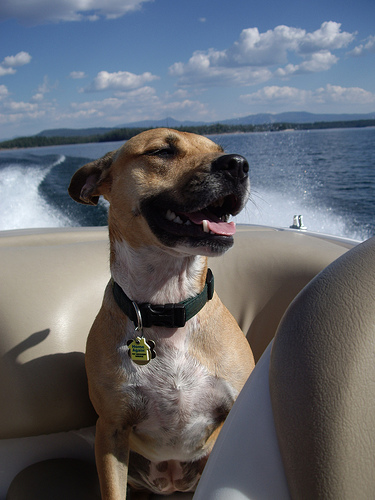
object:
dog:
[56, 96, 281, 461]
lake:
[2, 82, 359, 261]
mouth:
[150, 166, 253, 254]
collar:
[71, 234, 245, 343]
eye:
[136, 121, 197, 169]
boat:
[1, 140, 348, 409]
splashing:
[257, 159, 349, 222]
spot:
[143, 290, 224, 410]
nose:
[187, 144, 253, 189]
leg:
[75, 382, 142, 498]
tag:
[111, 326, 155, 371]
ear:
[35, 152, 125, 208]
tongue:
[143, 194, 261, 267]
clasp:
[142, 282, 216, 333]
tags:
[60, 262, 243, 374]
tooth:
[176, 206, 223, 261]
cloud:
[201, 19, 326, 100]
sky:
[102, 13, 296, 98]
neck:
[63, 212, 263, 319]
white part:
[115, 247, 199, 301]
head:
[46, 89, 290, 289]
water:
[285, 144, 339, 213]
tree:
[19, 86, 159, 152]